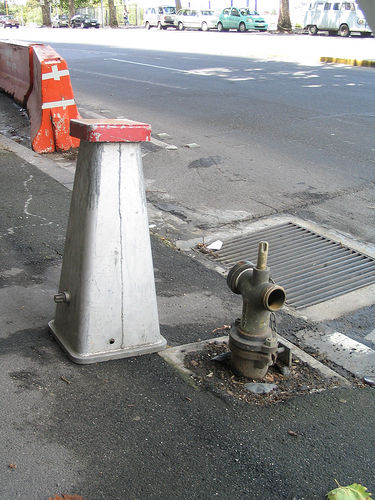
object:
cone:
[45, 108, 168, 363]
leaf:
[327, 475, 371, 500]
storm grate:
[197, 222, 374, 307]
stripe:
[318, 53, 375, 76]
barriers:
[1, 35, 82, 153]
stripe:
[106, 51, 203, 82]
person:
[123, 5, 132, 28]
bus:
[303, 0, 375, 38]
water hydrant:
[226, 234, 294, 382]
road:
[2, 24, 375, 350]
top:
[67, 115, 153, 147]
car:
[2, 16, 24, 30]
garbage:
[198, 235, 229, 257]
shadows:
[188, 57, 365, 93]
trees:
[32, 1, 124, 28]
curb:
[317, 48, 374, 70]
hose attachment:
[259, 280, 288, 311]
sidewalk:
[98, 22, 306, 35]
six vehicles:
[51, 3, 375, 35]